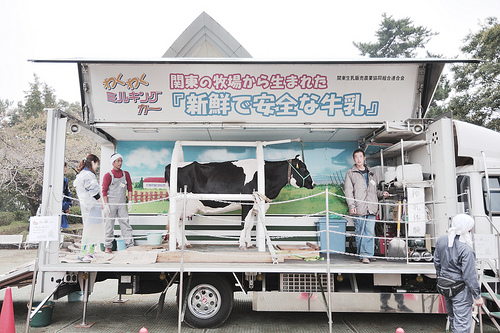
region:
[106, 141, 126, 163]
The white headband on the guy standing on the left.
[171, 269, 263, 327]
The tire under the platform.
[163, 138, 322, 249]
The cow on the truck.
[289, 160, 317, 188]
The green harness around the cow's face.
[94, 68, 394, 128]
The colorful words on the truck's sign.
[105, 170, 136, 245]
The overalls the guy on the left is wearing.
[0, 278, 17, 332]
The orange cone in the corner.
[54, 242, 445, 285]
The platform the people are standing on.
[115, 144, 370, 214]
The painted scenery behind the cow.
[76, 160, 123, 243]
The white jacket the lady is wearing on the left.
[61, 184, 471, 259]
The chain link ropes on the platform.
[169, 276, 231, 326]
The wheel of the truck.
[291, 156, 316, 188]
The green harness on the cow's face.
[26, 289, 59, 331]
The green bucket under the platform.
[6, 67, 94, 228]
The trees in the background on the left.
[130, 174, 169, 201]
The red post fence on the painted scenery.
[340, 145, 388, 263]
The man standing on the platform on the right.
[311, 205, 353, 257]
The blue trash can next to the man on the right of the platform.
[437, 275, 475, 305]
The black pack around the man's waist on the right.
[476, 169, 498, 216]
The window on the side of the truck.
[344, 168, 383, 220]
The gray coat the man on the right is wearing.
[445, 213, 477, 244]
The white headwrap/t-shirt the man on the right is wearing on his head.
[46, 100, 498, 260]
The rig of the truck.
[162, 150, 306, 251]
The cow on the platform.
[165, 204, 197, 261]
The back legs of the cow.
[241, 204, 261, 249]
The front legs of the cow.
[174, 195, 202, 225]
The utters of the cow.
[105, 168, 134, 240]
The overalls the man is wearing on the left.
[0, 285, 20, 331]
The orange cone in the corner..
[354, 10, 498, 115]
The trees in the background on the right.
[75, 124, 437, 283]
A cow on a trailer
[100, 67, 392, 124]
Asian writing is red and blue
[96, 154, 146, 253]
The man is wearing overalls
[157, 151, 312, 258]
The cow is black and white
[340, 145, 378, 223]
The man is wearing a gray coat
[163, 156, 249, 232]
This is a cow for milking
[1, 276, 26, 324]
An orange traffic cone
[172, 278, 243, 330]
The wheel on a trailer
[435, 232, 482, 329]
Person wearing green coveralls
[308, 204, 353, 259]
A blue plastic box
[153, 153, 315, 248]
a cow standing inside of a truck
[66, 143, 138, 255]
people standing inside of the truck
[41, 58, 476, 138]
the side wall of the truck pulled up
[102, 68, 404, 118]
writing on the side of the truck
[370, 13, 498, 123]
a green leafy tree in the background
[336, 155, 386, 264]
another man standing in the truck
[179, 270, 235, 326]
a wheel of the truck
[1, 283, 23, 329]
an orange cone sitting in the truck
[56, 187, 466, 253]
a metal fence next to the cow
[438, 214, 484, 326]
a man standing next to the truck